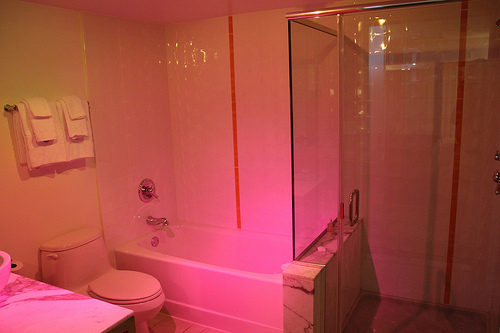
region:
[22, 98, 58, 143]
wash cloths hanging on rack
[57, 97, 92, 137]
wash cloths hanging on rack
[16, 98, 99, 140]
wash cloths hanging on rack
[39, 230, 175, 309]
toilet next to tub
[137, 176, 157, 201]
tub handle on wall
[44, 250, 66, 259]
toilet handle on tank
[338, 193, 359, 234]
shower handle on door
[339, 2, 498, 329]
glass shower door in bathroom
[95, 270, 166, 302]
toilet lid on toilet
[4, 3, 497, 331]
a bathroom with an enclosed shower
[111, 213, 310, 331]
a full tub is in the bathroom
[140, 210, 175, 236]
the faucet for the tub is in the wall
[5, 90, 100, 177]
towells are on a towel rack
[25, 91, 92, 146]
washcloths are folded on the guest towels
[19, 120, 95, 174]
the hand towels are folded on the bath towels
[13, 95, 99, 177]
the towels are folded on the towel rack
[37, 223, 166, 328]
a toilet is next to the bathtub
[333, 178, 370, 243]
the door handle is for the shower stall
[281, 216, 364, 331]
a marble wall divides the tub and shower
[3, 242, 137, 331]
Marble sink with red light shining on it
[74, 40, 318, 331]
Bath tub wall with red line going through it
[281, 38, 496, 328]
Clear glass shower stall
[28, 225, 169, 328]
Pink tinted toliet with closed lid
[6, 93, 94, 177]
Six bath towels on a rack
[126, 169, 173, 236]
Silver bath tub fixtures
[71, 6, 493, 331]
Bath and shower separated by marble wall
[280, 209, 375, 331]
Marble wall with white bar of soap on it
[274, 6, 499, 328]
Shower with silver fixtures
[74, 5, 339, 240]
Pink tinted wall with red line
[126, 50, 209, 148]
The wall is made of tiles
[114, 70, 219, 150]
The tiles are the color white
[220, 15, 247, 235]
The line is the color orange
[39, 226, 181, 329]
The toilet is against the wall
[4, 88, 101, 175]
The towels are the color white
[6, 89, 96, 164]
The towels hanging from the towel bar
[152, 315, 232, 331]
The floor is made of tiles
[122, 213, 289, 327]
The bathtub is the color white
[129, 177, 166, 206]
The shower handle is silver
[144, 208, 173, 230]
The bath faucet is silver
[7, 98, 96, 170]
White towels on the rack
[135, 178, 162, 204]
Stainless steel shower handle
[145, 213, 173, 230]
Stainless steel shower faucet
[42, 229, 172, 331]
Clean white toilet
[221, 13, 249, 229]
Orange stripe running vertically the wall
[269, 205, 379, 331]
Granite wall next to shower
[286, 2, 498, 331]
Clear glass door screen next to shower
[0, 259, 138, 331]
Granite sink counter corner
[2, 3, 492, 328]
Bathroom with bright red hue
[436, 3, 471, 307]
Orange strip running down the wall